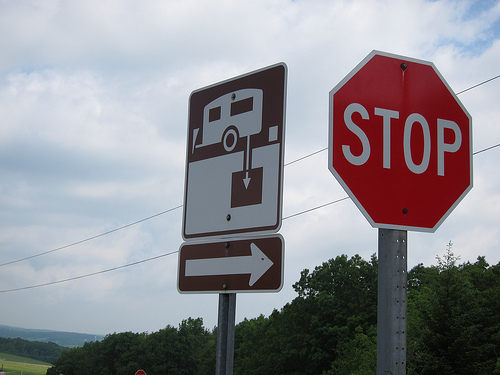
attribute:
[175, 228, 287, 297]
sign — white, black, arrow 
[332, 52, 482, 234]
stop sign — red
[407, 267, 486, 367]
tree — evergreen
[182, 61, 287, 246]
sign — black, white, brown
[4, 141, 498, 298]
wire — black, rubber, electrical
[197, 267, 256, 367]
pole — grey, metal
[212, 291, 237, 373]
pole — metal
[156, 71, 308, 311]
sign — brown 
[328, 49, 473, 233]
sign — red, white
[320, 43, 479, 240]
sign — red, octagonal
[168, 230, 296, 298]
arrow — white, brown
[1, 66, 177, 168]
cloud — white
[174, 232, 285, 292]
sign — brown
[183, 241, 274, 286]
arrow — white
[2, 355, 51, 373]
field — green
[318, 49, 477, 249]
street sign — red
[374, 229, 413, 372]
pole — metal 